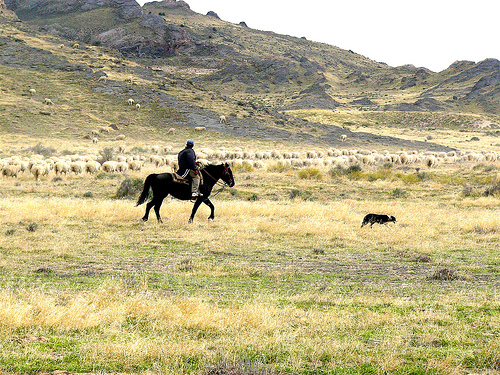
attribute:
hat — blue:
[184, 138, 196, 148]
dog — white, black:
[360, 211, 400, 231]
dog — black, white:
[350, 201, 384, 228]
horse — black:
[134, 160, 238, 224]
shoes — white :
[188, 185, 205, 202]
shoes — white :
[191, 190, 206, 197]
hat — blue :
[185, 140, 194, 145]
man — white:
[175, 143, 202, 203]